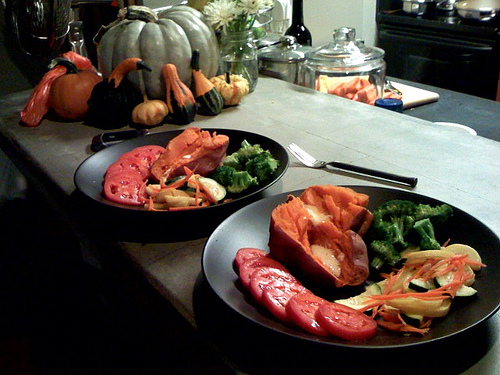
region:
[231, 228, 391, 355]
tomatoes on a plate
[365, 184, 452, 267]
broccoli on a plate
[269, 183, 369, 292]
sweet potato on a plate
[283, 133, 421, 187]
fork on a plate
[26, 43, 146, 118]
squash on the table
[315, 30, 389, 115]
jar on the table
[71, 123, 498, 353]
Two bowls of food on the table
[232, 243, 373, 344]
Slices of tomato on the plate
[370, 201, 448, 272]
Broccoli on the plate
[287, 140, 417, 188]
Fork behind the plates of food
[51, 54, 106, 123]
Orange pumpkin on the table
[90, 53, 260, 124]
Gourds around a silver pumpkin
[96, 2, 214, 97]
Silver pumpkin on the table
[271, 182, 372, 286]
Baked sweet potato with butter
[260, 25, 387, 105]
Two glass containers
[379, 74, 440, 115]
A white cutting board.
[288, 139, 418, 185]
A long fork.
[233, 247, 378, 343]
Six sliced tomatoes that are more visible.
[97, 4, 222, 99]
A large grey pumpkin on a counter.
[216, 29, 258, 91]
Clear mason jar.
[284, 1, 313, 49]
Black wine bottle.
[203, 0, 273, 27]
White flowers in a mason jar.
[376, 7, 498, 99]
A black oven.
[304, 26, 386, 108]
Larger clear glass container with knob on lid.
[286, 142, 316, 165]
Shiny tines of a fork.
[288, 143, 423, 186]
FORK LAYING ON THE TABLE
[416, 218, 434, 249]
BROCCOLI IN THE PAN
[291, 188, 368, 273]
SWEET POTATOE IN THE PAN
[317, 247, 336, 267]
BUTTER IN THE MIDDLE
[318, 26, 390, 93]
GLASS JAR ON THE COUNTER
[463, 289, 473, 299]
CUCUMBER IN THE PAN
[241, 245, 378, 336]
There is red piece of tomatoes on the dish.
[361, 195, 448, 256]
The brocilli is green.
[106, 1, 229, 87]
The pumpkin is painted gray.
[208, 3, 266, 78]
There are white flowers in the glass vase.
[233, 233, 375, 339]
Tomato slices on a plate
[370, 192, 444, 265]
Broccoli on thr plate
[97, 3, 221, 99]
Pumpkin on the table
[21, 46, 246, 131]
Gourds surrounding the pumpkin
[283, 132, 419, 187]
Fork with a black handle.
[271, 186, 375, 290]
Baked sweet potato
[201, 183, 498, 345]
Vegetables in a black bowl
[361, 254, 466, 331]
Skinny carrot slices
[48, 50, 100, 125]
Orange pumpkin on the table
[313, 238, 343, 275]
Melted butter on the baked sweet potato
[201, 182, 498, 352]
plate is on the table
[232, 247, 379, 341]
tomatoes are on the plate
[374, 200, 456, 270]
broccoli is on the plate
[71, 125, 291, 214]
plate is on the table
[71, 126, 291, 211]
plate is beside plate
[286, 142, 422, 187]
fork is on the table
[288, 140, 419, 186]
fork is in front of plate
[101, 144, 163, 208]
tomatoes are on the plate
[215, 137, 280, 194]
broccoli is on the plate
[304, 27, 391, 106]
jar is on the counter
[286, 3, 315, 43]
a black glass bottle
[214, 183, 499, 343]
the black plate has vegetables on it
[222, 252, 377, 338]
slices of red tomato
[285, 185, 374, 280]
a sweet potato with butter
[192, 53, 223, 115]
an orange and green gourd